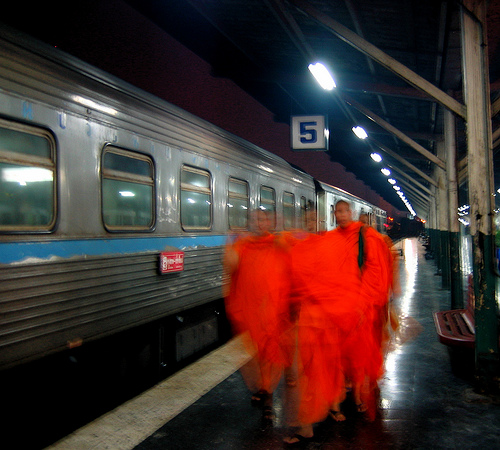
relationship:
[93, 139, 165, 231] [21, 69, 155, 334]
window in train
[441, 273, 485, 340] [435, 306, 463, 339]
bench has slits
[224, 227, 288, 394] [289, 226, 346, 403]
man wearing gown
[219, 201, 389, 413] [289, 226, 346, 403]
monks wearing gowns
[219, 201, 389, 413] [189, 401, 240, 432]
monks at platform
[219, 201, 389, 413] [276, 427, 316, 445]
monks wearing flip flop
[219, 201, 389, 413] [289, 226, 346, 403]
monks in orange